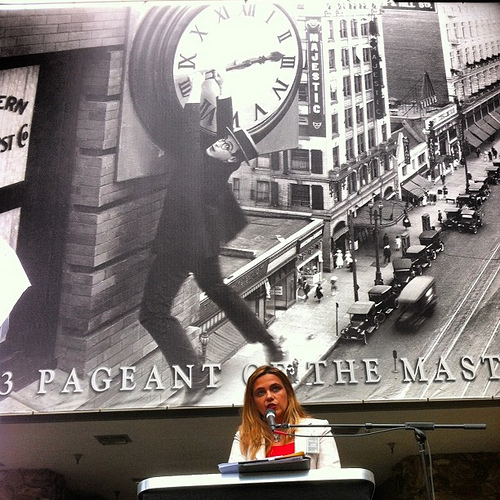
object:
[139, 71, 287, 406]
man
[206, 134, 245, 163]
head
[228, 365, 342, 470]
woman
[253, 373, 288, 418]
head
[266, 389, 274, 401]
nose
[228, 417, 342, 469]
jacket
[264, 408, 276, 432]
microphone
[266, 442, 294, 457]
shirt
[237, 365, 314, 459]
hair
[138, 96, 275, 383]
suit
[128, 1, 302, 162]
clock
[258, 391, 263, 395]
eyes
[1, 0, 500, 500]
photo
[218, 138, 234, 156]
glasses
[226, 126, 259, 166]
hat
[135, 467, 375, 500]
podium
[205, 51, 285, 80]
hands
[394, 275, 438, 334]
car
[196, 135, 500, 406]
street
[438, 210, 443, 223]
person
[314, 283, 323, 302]
person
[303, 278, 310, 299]
person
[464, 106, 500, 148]
awning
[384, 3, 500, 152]
building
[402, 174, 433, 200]
awning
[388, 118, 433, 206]
building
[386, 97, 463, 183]
building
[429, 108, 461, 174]
store front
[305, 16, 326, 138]
sign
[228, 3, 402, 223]
building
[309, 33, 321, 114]
majestic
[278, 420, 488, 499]
stand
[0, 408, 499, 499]
ceiling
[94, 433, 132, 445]
vent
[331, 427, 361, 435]
vent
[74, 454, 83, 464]
fire sprinkler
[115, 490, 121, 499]
fire sprinkler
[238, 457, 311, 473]
folder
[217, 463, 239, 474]
papers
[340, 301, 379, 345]
vehicle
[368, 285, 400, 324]
vehicle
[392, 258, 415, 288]
vehicle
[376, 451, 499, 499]
pillar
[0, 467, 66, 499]
pillar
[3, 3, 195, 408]
building